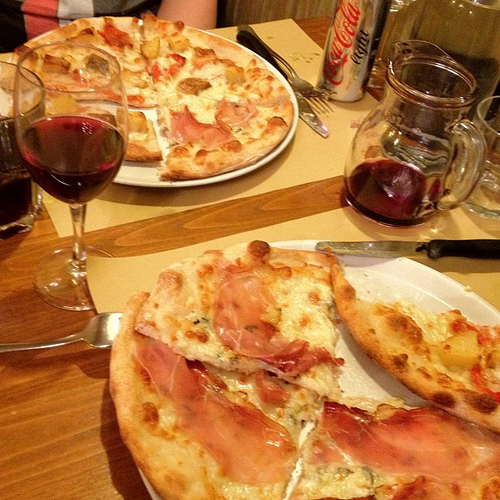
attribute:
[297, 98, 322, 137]
knife — black handled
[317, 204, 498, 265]
knife —  black, silver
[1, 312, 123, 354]
fork — silver 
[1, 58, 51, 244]
glass — wine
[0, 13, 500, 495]
table — wooden 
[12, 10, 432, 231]
papermat — paper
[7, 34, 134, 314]
glass — tall, stemmed, clear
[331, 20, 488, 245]
jar — glass , syrup 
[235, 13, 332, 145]
knife — black handled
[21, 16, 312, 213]
plate — round , white 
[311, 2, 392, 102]
can — silver, red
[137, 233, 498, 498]
white plate — ceramic, round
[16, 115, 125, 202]
wine — red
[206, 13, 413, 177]
fork — silver 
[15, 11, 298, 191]
plate — white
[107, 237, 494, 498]
plate — white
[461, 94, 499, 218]
glass — clear, empty